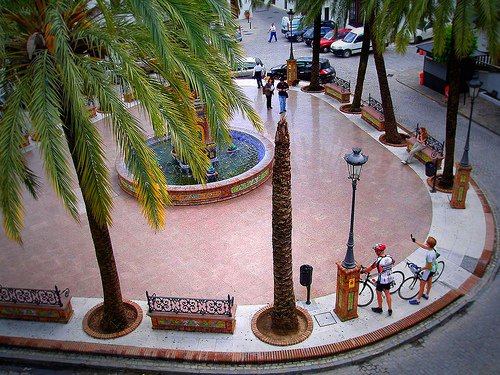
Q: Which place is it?
A: It is a city.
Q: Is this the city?
A: Yes, it is the city.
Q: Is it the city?
A: Yes, it is the city.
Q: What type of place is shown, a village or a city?
A: It is a city.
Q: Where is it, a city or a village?
A: It is a city.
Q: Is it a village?
A: No, it is a city.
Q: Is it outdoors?
A: Yes, it is outdoors.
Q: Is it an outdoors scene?
A: Yes, it is outdoors.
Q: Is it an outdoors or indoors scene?
A: It is outdoors.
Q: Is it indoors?
A: No, it is outdoors.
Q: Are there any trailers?
A: No, there are no trailers.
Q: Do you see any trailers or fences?
A: No, there are no trailers or fences.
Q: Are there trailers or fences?
A: No, there are no trailers or fences.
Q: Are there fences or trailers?
A: No, there are no trailers or fences.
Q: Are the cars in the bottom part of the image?
A: No, the cars are in the top of the image.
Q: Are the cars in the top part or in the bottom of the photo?
A: The cars are in the top of the image.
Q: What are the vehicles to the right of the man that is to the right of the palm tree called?
A: The vehicles are cars.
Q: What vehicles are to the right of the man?
A: The vehicles are cars.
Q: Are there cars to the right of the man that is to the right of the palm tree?
A: Yes, there are cars to the right of the man.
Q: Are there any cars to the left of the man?
A: No, the cars are to the right of the man.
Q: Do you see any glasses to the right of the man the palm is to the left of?
A: No, there are cars to the right of the man.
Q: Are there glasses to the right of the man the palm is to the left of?
A: No, there are cars to the right of the man.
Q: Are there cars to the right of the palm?
A: Yes, there are cars to the right of the palm.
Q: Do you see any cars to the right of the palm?
A: Yes, there are cars to the right of the palm.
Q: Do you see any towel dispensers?
A: No, there are no towel dispensers.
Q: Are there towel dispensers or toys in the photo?
A: No, there are no towel dispensers or toys.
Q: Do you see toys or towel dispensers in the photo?
A: No, there are no towel dispensers or toys.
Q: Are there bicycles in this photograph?
A: Yes, there are bicycles.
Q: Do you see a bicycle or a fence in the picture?
A: Yes, there are bicycles.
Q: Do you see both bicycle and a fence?
A: No, there are bicycles but no fences.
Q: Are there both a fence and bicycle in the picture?
A: No, there are bicycles but no fences.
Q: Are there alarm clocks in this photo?
A: No, there are no alarm clocks.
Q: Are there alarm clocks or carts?
A: No, there are no alarm clocks or carts.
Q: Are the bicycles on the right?
A: Yes, the bicycles are on the right of the image.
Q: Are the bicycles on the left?
A: No, the bicycles are on the right of the image.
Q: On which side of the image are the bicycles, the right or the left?
A: The bicycles are on the right of the image.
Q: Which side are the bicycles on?
A: The bicycles are on the right of the image.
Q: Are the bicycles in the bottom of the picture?
A: Yes, the bicycles are in the bottom of the image.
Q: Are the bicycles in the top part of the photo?
A: No, the bicycles are in the bottom of the image.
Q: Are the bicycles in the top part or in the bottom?
A: The bicycles are in the bottom of the image.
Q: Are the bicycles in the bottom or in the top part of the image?
A: The bicycles are in the bottom of the image.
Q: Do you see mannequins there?
A: No, there are no mannequins.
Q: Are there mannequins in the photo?
A: No, there are no mannequins.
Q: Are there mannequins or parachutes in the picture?
A: No, there are no mannequins or parachutes.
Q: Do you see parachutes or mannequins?
A: No, there are no mannequins or parachutes.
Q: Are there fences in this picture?
A: No, there are no fences.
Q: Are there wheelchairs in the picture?
A: No, there are no wheelchairs.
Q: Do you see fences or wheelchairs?
A: No, there are no wheelchairs or fences.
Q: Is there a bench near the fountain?
A: Yes, there are benches near the fountain.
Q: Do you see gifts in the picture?
A: No, there are no gifts.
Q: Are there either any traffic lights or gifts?
A: No, there are no gifts or traffic lights.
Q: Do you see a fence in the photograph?
A: No, there are no fences.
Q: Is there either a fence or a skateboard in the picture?
A: No, there are no fences or skateboards.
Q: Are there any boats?
A: No, there are no boats.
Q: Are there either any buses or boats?
A: No, there are no boats or buses.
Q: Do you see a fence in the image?
A: No, there are no fences.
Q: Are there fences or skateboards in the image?
A: No, there are no fences or skateboards.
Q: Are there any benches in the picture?
A: Yes, there is a bench.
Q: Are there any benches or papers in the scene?
A: Yes, there is a bench.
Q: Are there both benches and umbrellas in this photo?
A: No, there is a bench but no umbrellas.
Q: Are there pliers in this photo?
A: No, there are no pliers.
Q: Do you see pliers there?
A: No, there are no pliers.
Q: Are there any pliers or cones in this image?
A: No, there are no pliers or cones.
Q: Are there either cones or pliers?
A: No, there are no pliers or cones.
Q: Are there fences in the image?
A: No, there are no fences.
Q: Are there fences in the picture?
A: No, there are no fences.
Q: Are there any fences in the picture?
A: No, there are no fences.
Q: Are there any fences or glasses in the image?
A: No, there are no fences or glasses.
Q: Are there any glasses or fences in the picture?
A: No, there are no fences or glasses.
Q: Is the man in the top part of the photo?
A: Yes, the man is in the top of the image.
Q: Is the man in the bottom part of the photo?
A: No, the man is in the top of the image.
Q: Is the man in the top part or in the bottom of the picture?
A: The man is in the top of the image.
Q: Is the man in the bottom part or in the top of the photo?
A: The man is in the top of the image.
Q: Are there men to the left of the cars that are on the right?
A: Yes, there is a man to the left of the cars.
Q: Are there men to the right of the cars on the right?
A: No, the man is to the left of the cars.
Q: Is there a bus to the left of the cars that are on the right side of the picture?
A: No, there is a man to the left of the cars.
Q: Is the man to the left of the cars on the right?
A: Yes, the man is to the left of the cars.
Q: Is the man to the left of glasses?
A: No, the man is to the left of the cars.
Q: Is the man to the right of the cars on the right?
A: No, the man is to the left of the cars.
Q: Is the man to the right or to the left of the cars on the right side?
A: The man is to the left of the cars.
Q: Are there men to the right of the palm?
A: Yes, there is a man to the right of the palm.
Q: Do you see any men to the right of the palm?
A: Yes, there is a man to the right of the palm.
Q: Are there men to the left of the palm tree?
A: No, the man is to the right of the palm tree.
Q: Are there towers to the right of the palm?
A: No, there is a man to the right of the palm.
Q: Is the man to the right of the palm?
A: Yes, the man is to the right of the palm.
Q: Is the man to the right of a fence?
A: No, the man is to the right of the palm.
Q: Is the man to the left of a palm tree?
A: No, the man is to the right of a palm tree.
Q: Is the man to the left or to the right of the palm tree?
A: The man is to the right of the palm tree.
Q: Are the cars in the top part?
A: Yes, the cars are in the top of the image.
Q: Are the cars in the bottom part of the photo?
A: No, the cars are in the top of the image.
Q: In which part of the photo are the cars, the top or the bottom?
A: The cars are in the top of the image.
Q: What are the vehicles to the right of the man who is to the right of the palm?
A: The vehicles are cars.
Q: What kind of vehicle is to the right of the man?
A: The vehicles are cars.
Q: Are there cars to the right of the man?
A: Yes, there are cars to the right of the man.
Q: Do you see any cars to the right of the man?
A: Yes, there are cars to the right of the man.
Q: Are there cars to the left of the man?
A: No, the cars are to the right of the man.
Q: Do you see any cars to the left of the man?
A: No, the cars are to the right of the man.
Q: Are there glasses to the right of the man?
A: No, there are cars to the right of the man.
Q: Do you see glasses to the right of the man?
A: No, there are cars to the right of the man.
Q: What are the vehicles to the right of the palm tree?
A: The vehicles are cars.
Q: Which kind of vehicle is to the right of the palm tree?
A: The vehicles are cars.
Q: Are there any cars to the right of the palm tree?
A: Yes, there are cars to the right of the palm tree.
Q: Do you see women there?
A: Yes, there is a woman.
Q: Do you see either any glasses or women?
A: Yes, there is a woman.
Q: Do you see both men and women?
A: Yes, there are both a woman and a man.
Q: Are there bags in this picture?
A: No, there are no bags.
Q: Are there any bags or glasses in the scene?
A: No, there are no bags or glasses.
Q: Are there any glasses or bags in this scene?
A: No, there are no bags or glasses.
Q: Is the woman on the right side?
A: Yes, the woman is on the right of the image.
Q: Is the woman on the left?
A: No, the woman is on the right of the image.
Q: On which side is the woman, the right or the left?
A: The woman is on the right of the image.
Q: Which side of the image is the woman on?
A: The woman is on the right of the image.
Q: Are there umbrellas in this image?
A: No, there are no umbrellas.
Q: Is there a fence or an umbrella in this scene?
A: No, there are no umbrellas or fences.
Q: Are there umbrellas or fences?
A: No, there are no umbrellas or fences.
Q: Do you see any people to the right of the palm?
A: Yes, there are people to the right of the palm.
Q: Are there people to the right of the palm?
A: Yes, there are people to the right of the palm.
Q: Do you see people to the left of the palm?
A: No, the people are to the right of the palm.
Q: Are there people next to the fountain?
A: Yes, there are people next to the fountain.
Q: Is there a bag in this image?
A: No, there are no bags.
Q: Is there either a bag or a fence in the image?
A: No, there are no bags or fences.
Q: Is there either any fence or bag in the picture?
A: No, there are no bags or fences.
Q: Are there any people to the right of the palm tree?
A: Yes, there are people to the right of the palm tree.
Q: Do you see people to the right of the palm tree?
A: Yes, there are people to the right of the palm tree.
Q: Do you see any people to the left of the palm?
A: No, the people are to the right of the palm.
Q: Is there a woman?
A: Yes, there is a woman.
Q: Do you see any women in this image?
A: Yes, there is a woman.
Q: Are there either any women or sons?
A: Yes, there is a woman.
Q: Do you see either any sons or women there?
A: Yes, there is a woman.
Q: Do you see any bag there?
A: No, there are no bags.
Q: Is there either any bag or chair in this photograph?
A: No, there are no bags or chairs.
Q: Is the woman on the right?
A: Yes, the woman is on the right of the image.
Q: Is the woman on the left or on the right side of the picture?
A: The woman is on the right of the image.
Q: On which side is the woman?
A: The woman is on the right of the image.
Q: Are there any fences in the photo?
A: No, there are no fences.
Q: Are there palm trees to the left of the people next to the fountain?
A: Yes, there is a palm tree to the left of the people.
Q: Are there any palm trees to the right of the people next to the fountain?
A: No, the palm tree is to the left of the people.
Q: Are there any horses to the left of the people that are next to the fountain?
A: No, there is a palm tree to the left of the people.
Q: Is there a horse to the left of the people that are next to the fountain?
A: No, there is a palm tree to the left of the people.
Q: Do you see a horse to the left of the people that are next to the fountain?
A: No, there is a palm tree to the left of the people.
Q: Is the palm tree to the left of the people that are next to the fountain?
A: Yes, the palm tree is to the left of the people.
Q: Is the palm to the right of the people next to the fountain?
A: No, the palm is to the left of the people.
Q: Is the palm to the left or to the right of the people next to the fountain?
A: The palm is to the left of the people.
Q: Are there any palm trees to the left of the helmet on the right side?
A: Yes, there is a palm tree to the left of the helmet.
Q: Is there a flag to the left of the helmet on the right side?
A: No, there is a palm tree to the left of the helmet.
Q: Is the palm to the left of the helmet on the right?
A: Yes, the palm is to the left of the helmet.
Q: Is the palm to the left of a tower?
A: No, the palm is to the left of the helmet.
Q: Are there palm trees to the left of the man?
A: Yes, there is a palm tree to the left of the man.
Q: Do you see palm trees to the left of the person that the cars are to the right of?
A: Yes, there is a palm tree to the left of the man.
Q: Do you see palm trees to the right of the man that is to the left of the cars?
A: No, the palm tree is to the left of the man.